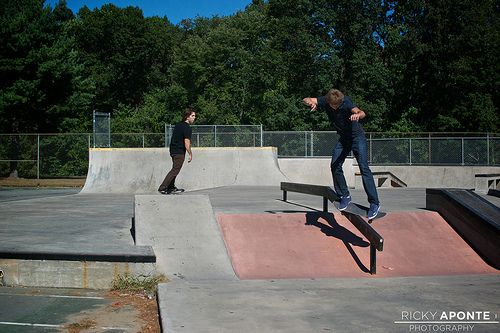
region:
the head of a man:
[324, 86, 348, 111]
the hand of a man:
[345, 109, 365, 123]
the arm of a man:
[349, 100, 368, 120]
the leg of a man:
[350, 136, 382, 206]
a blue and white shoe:
[364, 196, 383, 221]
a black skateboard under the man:
[328, 195, 388, 222]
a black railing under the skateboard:
[276, 177, 389, 274]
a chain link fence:
[0, 108, 499, 181]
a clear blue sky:
[39, 0, 430, 65]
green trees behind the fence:
[0, 0, 498, 180]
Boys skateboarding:
[146, 88, 384, 220]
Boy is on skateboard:
[301, 82, 386, 219]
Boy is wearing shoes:
[337, 192, 383, 219]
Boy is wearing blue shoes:
[337, 192, 382, 219]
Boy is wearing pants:
[325, 134, 382, 206]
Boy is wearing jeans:
[328, 132, 383, 206]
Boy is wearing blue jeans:
[325, 135, 381, 207]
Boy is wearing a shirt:
[314, 92, 366, 141]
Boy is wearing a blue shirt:
[315, 93, 366, 138]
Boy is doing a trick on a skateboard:
[301, 90, 390, 222]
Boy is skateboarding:
[152, 102, 198, 195]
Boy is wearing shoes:
[157, 185, 187, 196]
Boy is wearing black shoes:
[155, 185, 185, 196]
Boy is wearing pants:
[156, 150, 188, 190]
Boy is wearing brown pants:
[160, 147, 187, 192]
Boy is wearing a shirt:
[166, 117, 194, 155]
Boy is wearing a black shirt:
[167, 121, 192, 155]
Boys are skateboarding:
[150, 87, 388, 226]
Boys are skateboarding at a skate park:
[156, 84, 392, 224]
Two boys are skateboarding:
[137, 87, 388, 234]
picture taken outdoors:
[75, 61, 499, 331]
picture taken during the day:
[26, 4, 400, 329]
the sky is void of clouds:
[172, 6, 209, 22]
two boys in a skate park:
[106, 41, 454, 281]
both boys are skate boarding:
[111, 90, 464, 254]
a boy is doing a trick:
[301, 93, 424, 263]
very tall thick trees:
[30, 23, 457, 100]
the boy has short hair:
[328, 90, 343, 108]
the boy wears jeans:
[337, 156, 374, 197]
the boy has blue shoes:
[339, 201, 381, 221]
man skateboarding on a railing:
[303, 78, 399, 233]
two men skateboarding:
[136, 87, 410, 236]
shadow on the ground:
[272, 193, 372, 279]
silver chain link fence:
[76, 105, 499, 175]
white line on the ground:
[2, 313, 54, 330]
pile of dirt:
[60, 289, 160, 328]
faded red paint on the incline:
[217, 205, 477, 278]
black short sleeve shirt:
[164, 119, 194, 154]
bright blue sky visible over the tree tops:
[46, 1, 258, 36]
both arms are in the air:
[301, 93, 381, 127]